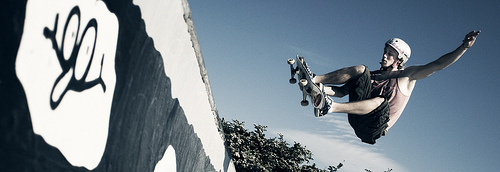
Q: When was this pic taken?
A: During the day.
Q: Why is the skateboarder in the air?
A: Doing a trick.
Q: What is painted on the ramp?
A: Graffiti.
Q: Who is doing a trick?
A: A skateboarder.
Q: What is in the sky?
A: Clouds.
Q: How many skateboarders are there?
A: 1.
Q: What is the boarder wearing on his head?
A: Helmet.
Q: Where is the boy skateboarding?
A: Skatepark.